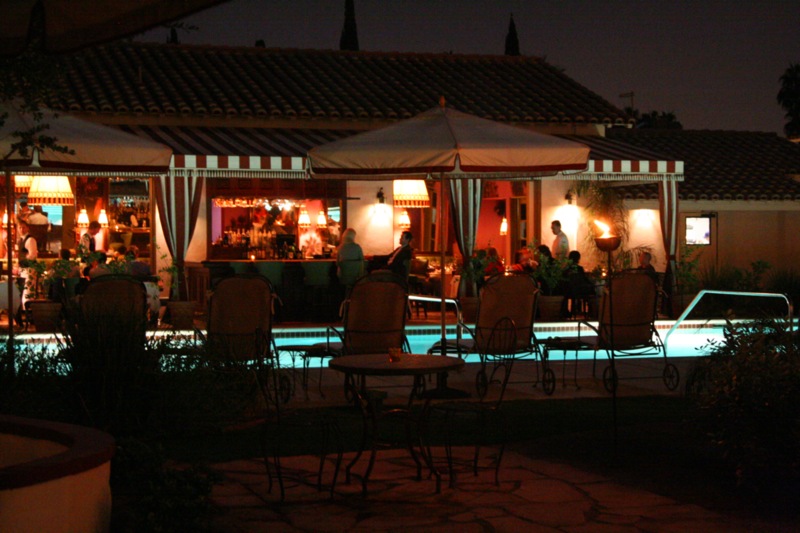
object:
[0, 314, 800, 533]
building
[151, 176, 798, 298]
wall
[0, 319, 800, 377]
pool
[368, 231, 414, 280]
man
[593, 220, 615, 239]
fire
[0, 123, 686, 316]
awning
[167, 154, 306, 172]
bar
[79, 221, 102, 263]
waiter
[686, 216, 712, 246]
window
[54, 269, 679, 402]
chairs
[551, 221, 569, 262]
man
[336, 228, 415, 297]
people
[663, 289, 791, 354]
railing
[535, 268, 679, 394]
chair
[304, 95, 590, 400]
umbrella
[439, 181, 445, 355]
pole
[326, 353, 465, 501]
table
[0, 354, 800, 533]
deck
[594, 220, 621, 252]
torch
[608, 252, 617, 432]
pole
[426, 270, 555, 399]
chair